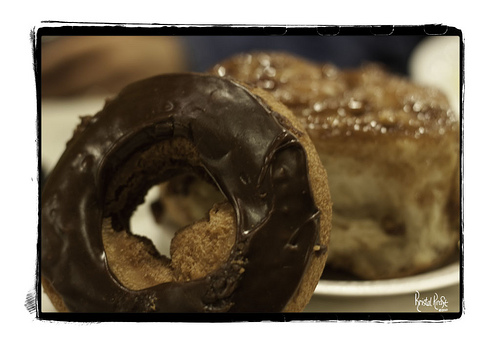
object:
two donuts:
[41, 50, 456, 312]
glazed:
[117, 102, 164, 139]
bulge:
[168, 200, 237, 284]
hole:
[135, 180, 200, 243]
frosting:
[42, 70, 308, 321]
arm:
[41, 35, 429, 100]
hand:
[42, 35, 188, 97]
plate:
[311, 250, 460, 300]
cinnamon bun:
[151, 47, 462, 274]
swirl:
[250, 130, 305, 207]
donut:
[39, 67, 330, 316]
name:
[409, 290, 452, 315]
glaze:
[213, 48, 460, 138]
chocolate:
[243, 174, 275, 236]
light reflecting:
[65, 125, 125, 182]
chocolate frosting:
[40, 190, 93, 268]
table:
[45, 93, 459, 309]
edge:
[331, 271, 453, 300]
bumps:
[217, 111, 311, 306]